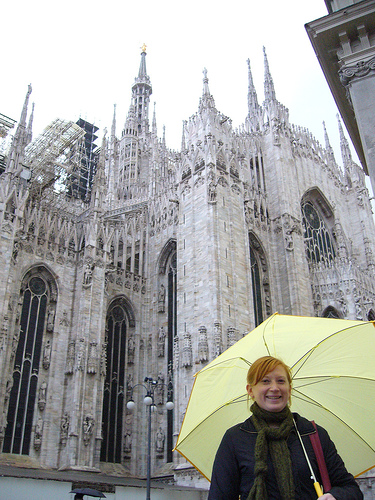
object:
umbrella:
[65, 485, 106, 498]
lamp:
[126, 375, 174, 413]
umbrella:
[188, 295, 374, 427]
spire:
[20, 80, 32, 128]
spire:
[135, 44, 150, 75]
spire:
[197, 67, 215, 98]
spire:
[257, 41, 273, 77]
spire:
[110, 106, 118, 147]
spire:
[244, 61, 256, 93]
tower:
[244, 56, 258, 116]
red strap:
[307, 419, 333, 493]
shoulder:
[295, 413, 331, 434]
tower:
[258, 41, 292, 123]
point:
[200, 68, 215, 109]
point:
[246, 55, 258, 110]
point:
[263, 46, 275, 102]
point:
[133, 41, 152, 131]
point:
[151, 100, 157, 131]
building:
[0, 44, 374, 499]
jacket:
[206, 402, 363, 498]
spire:
[334, 112, 355, 177]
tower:
[336, 118, 362, 188]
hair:
[246, 356, 293, 410]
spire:
[149, 98, 161, 137]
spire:
[316, 118, 341, 162]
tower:
[181, 63, 236, 185]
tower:
[6, 80, 39, 172]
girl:
[206, 353, 367, 500]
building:
[304, 0, 374, 196]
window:
[2, 262, 58, 458]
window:
[99, 296, 134, 463]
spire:
[133, 42, 149, 82]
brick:
[228, 224, 244, 236]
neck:
[251, 403, 293, 431]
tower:
[116, 40, 169, 156]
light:
[144, 396, 157, 405]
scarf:
[248, 403, 298, 499]